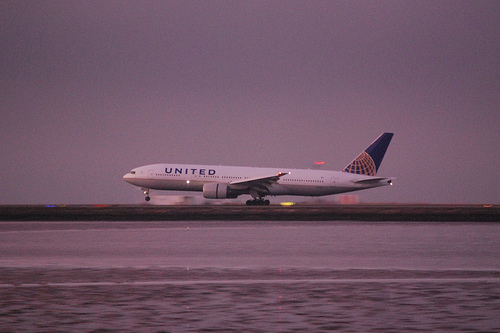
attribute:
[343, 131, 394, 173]
tail — blue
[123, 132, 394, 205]
airplane — a jet, white, commercial airliner, about to land, from united, large, jet, landing, a 747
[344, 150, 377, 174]
design — orange, a grid, globe shaped, yellow, curved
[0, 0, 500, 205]
sky — blue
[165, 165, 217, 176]
writing — united, blue, united logo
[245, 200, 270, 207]
back wheels — black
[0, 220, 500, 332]
water — calm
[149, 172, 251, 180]
passenger windows — small